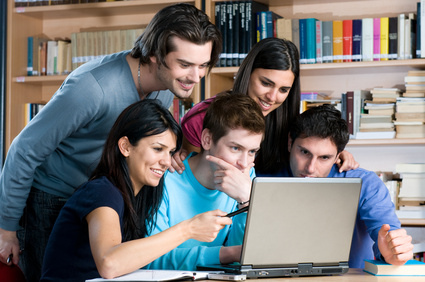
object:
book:
[85, 268, 210, 282]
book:
[364, 259, 424, 276]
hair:
[88, 96, 182, 234]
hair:
[130, 3, 221, 75]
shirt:
[0, 49, 179, 230]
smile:
[149, 166, 166, 177]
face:
[128, 125, 180, 187]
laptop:
[196, 175, 361, 278]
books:
[25, 36, 35, 75]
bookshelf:
[2, 0, 191, 137]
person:
[285, 102, 417, 267]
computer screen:
[239, 176, 362, 276]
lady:
[38, 98, 233, 282]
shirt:
[40, 175, 146, 282]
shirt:
[141, 149, 263, 274]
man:
[142, 91, 267, 272]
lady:
[168, 35, 359, 175]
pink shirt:
[182, 95, 221, 146]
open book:
[81, 268, 225, 282]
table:
[246, 275, 422, 281]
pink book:
[371, 15, 381, 61]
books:
[359, 130, 395, 140]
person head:
[134, 1, 221, 100]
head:
[286, 105, 352, 179]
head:
[200, 92, 267, 176]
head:
[113, 97, 182, 187]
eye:
[152, 145, 165, 152]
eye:
[228, 145, 243, 153]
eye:
[249, 149, 259, 155]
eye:
[168, 149, 177, 157]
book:
[388, 16, 397, 60]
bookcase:
[201, 1, 425, 228]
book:
[346, 91, 354, 135]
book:
[331, 17, 345, 62]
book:
[342, 20, 351, 61]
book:
[351, 18, 362, 62]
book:
[359, 17, 375, 61]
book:
[379, 15, 390, 60]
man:
[0, 3, 224, 280]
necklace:
[131, 56, 150, 98]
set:
[206, 0, 263, 71]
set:
[0, 1, 152, 73]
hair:
[233, 36, 304, 168]